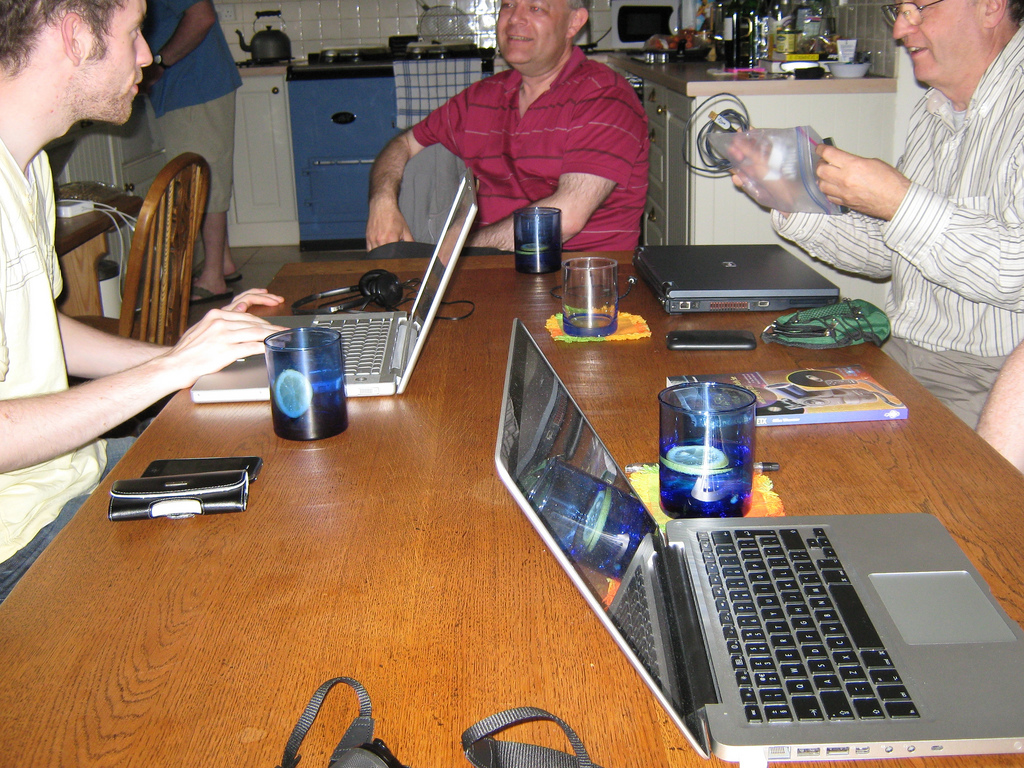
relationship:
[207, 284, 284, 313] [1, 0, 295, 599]
hand on man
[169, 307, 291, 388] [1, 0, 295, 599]
hand on man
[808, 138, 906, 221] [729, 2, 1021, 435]
hand on man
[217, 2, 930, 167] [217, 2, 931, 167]
wall on wall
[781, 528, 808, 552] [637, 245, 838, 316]
key on laptop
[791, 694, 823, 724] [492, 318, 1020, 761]
key on laptop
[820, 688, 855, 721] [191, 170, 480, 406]
key on laptop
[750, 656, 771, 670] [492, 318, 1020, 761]
key on laptop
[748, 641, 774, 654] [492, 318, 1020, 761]
key on laptop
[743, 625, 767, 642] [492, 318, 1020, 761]
key on laptop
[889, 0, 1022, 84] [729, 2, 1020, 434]
head of man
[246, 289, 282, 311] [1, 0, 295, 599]
finger of man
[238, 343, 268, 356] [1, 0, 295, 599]
finger of man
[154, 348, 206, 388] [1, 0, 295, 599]
wrist of man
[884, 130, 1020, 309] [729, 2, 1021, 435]
arm of man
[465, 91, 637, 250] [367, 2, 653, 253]
arm of man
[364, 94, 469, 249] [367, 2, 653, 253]
arm of man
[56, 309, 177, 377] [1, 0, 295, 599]
arm of man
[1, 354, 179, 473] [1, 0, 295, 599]
arm of man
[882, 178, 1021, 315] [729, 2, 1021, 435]
sleeve of man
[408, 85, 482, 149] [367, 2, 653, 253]
sleeve of man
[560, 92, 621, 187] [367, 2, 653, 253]
sleeve of man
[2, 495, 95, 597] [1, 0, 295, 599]
pants of man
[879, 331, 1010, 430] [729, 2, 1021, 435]
pants of man